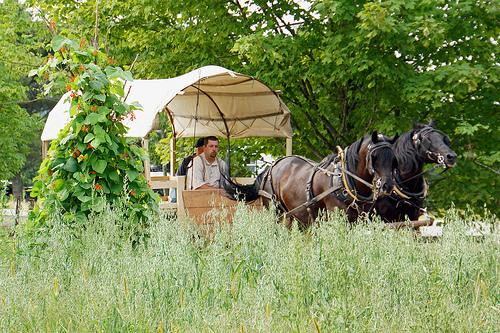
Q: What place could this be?
A: It is a field.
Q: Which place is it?
A: It is a field.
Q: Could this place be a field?
A: Yes, it is a field.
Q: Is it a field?
A: Yes, it is a field.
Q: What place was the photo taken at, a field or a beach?
A: It was taken at a field.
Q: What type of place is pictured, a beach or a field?
A: It is a field.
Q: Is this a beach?
A: No, it is a field.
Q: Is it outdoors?
A: Yes, it is outdoors.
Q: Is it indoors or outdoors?
A: It is outdoors.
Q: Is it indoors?
A: No, it is outdoors.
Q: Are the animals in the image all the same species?
A: Yes, all the animals are horses.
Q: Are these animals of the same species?
A: Yes, all the animals are horses.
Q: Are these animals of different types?
A: No, all the animals are horses.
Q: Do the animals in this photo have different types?
A: No, all the animals are horses.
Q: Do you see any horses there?
A: Yes, there is a horse.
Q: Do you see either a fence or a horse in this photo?
A: Yes, there is a horse.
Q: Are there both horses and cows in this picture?
A: No, there is a horse but no cows.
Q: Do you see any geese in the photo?
A: No, there are no geese.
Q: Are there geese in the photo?
A: No, there are no geese.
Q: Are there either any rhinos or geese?
A: No, there are no geese or rhinos.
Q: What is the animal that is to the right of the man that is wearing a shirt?
A: The animal is a horse.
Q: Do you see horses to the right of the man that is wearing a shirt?
A: Yes, there is a horse to the right of the man.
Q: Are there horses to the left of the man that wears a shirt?
A: No, the horse is to the right of the man.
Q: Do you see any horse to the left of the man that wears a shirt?
A: No, the horse is to the right of the man.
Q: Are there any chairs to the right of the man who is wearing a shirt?
A: No, there is a horse to the right of the man.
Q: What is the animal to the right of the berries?
A: The animal is a horse.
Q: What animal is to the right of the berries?
A: The animal is a horse.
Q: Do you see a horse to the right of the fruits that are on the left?
A: Yes, there is a horse to the right of the berries.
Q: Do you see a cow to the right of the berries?
A: No, there is a horse to the right of the berries.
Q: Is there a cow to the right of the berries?
A: No, there is a horse to the right of the berries.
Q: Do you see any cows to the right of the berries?
A: No, there is a horse to the right of the berries.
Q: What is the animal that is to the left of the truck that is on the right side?
A: The animal is a horse.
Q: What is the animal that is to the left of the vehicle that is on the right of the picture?
A: The animal is a horse.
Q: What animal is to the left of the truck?
A: The animal is a horse.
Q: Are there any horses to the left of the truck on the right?
A: Yes, there is a horse to the left of the truck.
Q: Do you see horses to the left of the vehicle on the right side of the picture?
A: Yes, there is a horse to the left of the truck.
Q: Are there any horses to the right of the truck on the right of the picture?
A: No, the horse is to the left of the truck.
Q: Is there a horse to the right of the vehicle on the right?
A: No, the horse is to the left of the truck.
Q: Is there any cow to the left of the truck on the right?
A: No, there is a horse to the left of the truck.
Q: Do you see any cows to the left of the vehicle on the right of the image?
A: No, there is a horse to the left of the truck.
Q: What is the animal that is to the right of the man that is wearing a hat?
A: The animal is a horse.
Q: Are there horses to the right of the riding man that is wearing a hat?
A: Yes, there is a horse to the right of the man.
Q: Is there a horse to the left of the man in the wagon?
A: No, the horse is to the right of the man.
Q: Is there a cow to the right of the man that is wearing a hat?
A: No, there is a horse to the right of the man.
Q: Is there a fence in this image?
A: No, there are no fences.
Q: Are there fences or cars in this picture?
A: No, there are no fences or cars.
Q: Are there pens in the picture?
A: No, there are no pens.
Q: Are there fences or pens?
A: No, there are no pens or fences.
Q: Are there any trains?
A: No, there are no trains.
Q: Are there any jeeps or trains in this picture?
A: No, there are no trains or jeeps.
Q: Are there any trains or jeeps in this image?
A: No, there are no trains or jeeps.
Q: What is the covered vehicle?
A: The vehicle is a wagon.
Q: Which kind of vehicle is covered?
A: The vehicle is a wagon.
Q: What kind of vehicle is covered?
A: The vehicle is a wagon.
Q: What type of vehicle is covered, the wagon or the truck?
A: The wagon is covered.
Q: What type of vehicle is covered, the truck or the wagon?
A: The wagon is covered.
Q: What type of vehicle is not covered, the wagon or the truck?
A: The truck is not covered.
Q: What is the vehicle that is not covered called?
A: The vehicle is a truck.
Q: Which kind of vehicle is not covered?
A: The vehicle is a truck.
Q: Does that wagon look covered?
A: Yes, the wagon is covered.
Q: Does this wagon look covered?
A: Yes, the wagon is covered.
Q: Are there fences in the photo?
A: No, there are no fences.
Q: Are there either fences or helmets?
A: No, there are no fences or helmets.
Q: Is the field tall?
A: Yes, the field is tall.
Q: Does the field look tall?
A: Yes, the field is tall.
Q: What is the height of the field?
A: The field is tall.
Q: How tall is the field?
A: The field is tall.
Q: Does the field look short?
A: No, the field is tall.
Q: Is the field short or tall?
A: The field is tall.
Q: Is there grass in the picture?
A: Yes, there is grass.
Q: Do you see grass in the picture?
A: Yes, there is grass.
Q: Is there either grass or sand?
A: Yes, there is grass.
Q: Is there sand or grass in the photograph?
A: Yes, there is grass.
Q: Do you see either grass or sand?
A: Yes, there is grass.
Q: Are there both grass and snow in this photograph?
A: No, there is grass but no snow.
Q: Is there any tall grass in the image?
A: Yes, there is tall grass.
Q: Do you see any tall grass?
A: Yes, there is tall grass.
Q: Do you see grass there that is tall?
A: Yes, there is grass that is tall.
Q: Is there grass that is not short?
A: Yes, there is tall grass.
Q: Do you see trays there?
A: No, there are no trays.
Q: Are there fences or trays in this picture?
A: No, there are no trays or fences.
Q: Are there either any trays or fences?
A: No, there are no trays or fences.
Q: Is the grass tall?
A: Yes, the grass is tall.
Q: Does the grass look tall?
A: Yes, the grass is tall.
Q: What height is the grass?
A: The grass is tall.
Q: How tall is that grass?
A: The grass is tall.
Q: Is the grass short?
A: No, the grass is tall.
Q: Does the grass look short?
A: No, the grass is tall.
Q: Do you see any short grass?
A: No, there is grass but it is tall.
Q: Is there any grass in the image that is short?
A: No, there is grass but it is tall.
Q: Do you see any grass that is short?
A: No, there is grass but it is tall.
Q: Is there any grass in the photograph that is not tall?
A: No, there is grass but it is tall.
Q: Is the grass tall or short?
A: The grass is tall.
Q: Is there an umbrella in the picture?
A: No, there are no umbrellas.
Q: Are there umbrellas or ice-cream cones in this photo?
A: No, there are no umbrellas or ice-cream cones.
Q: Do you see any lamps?
A: No, there are no lamps.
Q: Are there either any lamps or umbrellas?
A: No, there are no lamps or umbrellas.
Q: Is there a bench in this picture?
A: Yes, there is a bench.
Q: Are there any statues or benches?
A: Yes, there is a bench.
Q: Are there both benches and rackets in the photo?
A: No, there is a bench but no rackets.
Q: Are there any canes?
A: No, there are no canes.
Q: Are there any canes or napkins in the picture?
A: No, there are no canes or napkins.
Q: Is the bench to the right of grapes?
A: No, the bench is to the right of the berries.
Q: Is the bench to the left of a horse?
A: Yes, the bench is to the left of a horse.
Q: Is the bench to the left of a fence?
A: No, the bench is to the left of a horse.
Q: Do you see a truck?
A: Yes, there is a truck.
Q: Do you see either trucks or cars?
A: Yes, there is a truck.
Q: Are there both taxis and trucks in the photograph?
A: No, there is a truck but no taxis.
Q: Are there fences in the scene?
A: No, there are no fences.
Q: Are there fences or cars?
A: No, there are no fences or cars.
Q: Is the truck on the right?
A: Yes, the truck is on the right of the image.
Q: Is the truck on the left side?
A: No, the truck is on the right of the image.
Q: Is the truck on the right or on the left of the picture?
A: The truck is on the right of the image.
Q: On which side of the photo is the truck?
A: The truck is on the right of the image.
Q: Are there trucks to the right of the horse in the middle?
A: Yes, there is a truck to the right of the horse.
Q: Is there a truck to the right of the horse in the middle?
A: Yes, there is a truck to the right of the horse.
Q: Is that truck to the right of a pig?
A: No, the truck is to the right of the horse.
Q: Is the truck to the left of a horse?
A: No, the truck is to the right of a horse.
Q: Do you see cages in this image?
A: No, there are no cages.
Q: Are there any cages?
A: No, there are no cages.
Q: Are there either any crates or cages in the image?
A: No, there are no cages or crates.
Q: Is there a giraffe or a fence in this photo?
A: No, there are no fences or giraffes.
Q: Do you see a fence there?
A: No, there are no fences.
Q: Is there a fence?
A: No, there are no fences.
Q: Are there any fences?
A: No, there are no fences.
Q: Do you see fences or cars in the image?
A: No, there are no fences or cars.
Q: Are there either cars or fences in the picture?
A: No, there are no fences or cars.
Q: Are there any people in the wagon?
A: Yes, there are people in the wagon.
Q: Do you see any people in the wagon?
A: Yes, there are people in the wagon.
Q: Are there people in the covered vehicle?
A: Yes, there are people in the wagon.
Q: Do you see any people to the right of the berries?
A: Yes, there are people to the right of the berries.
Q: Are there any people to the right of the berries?
A: Yes, there are people to the right of the berries.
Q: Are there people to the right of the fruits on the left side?
A: Yes, there are people to the right of the berries.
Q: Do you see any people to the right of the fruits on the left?
A: Yes, there are people to the right of the berries.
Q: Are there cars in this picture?
A: No, there are no cars.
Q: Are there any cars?
A: No, there are no cars.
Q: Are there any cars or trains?
A: No, there are no cars or trains.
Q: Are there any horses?
A: Yes, there are horses.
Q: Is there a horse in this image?
A: Yes, there are horses.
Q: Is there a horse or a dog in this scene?
A: Yes, there are horses.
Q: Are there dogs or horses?
A: Yes, there are horses.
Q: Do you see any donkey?
A: No, there are no donkeys.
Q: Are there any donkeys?
A: No, there are no donkeys.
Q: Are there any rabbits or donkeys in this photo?
A: No, there are no donkeys or rabbits.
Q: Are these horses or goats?
A: These are horses.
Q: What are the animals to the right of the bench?
A: The animals are horses.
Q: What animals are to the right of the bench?
A: The animals are horses.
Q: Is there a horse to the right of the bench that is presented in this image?
A: Yes, there are horses to the right of the bench.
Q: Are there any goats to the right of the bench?
A: No, there are horses to the right of the bench.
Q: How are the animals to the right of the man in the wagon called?
A: The animals are horses.